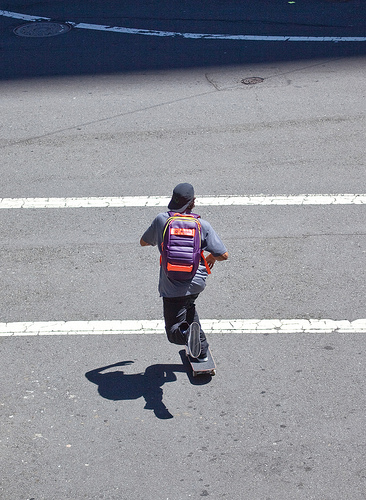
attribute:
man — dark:
[137, 184, 227, 363]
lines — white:
[0, 8, 364, 43]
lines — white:
[1, 191, 364, 207]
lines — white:
[1, 318, 364, 337]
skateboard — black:
[186, 346, 217, 381]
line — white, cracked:
[0, 169, 364, 224]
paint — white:
[262, 185, 356, 211]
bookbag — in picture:
[159, 211, 202, 285]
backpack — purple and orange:
[159, 215, 202, 281]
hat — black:
[163, 180, 196, 213]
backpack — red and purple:
[158, 211, 210, 282]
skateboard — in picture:
[180, 337, 219, 376]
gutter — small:
[222, 69, 255, 90]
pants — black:
[159, 291, 207, 338]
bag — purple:
[157, 212, 202, 278]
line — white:
[29, 189, 80, 265]